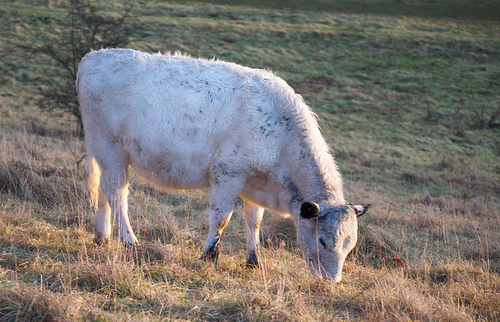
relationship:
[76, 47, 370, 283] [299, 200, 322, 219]
cow has ear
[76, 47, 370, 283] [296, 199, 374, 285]
cow has head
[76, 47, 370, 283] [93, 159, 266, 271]
cow has legs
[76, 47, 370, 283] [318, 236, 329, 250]
cow has eye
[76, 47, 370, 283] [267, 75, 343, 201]
cow has mane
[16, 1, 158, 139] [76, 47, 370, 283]
tree behind cow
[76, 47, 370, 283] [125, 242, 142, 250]
cow has hoof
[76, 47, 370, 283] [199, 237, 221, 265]
cow has marking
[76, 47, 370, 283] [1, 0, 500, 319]
animal in pasture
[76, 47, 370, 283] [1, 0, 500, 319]
animal eating grass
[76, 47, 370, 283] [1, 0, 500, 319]
cow on farm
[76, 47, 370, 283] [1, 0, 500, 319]
cow in grass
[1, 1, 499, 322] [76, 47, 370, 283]
picture of cow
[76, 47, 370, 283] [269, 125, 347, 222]
cow has neck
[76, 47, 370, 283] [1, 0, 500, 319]
cow eating grass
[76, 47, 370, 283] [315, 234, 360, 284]
cow has face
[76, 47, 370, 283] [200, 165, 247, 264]
cow has leg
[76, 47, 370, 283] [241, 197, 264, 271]
cow has leg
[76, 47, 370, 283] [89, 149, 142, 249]
cow has leg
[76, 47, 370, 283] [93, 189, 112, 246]
cow has leg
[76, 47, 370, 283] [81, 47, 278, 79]
cow has back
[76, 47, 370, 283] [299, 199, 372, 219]
cow has ears